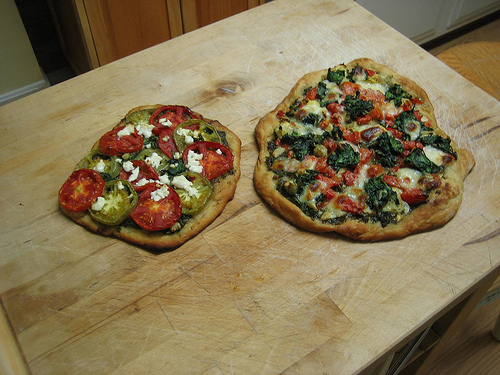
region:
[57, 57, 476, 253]
two home made vegetable pizzas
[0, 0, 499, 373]
pizzas on wooden scratched table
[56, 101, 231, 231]
green and red tomato slices on left pizza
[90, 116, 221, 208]
feta cheese on left pizza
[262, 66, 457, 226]
spinach on right pizza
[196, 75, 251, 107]
dark spot on wooden table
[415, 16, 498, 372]
wooden floor underneath table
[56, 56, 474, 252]
both pizzas have bread crusts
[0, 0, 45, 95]
yellow wall behind table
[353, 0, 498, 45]
white cabinets behind table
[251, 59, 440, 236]
this is a pizza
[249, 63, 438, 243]
the pizza is big in color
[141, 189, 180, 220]
the tomato is on the pizza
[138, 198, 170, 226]
the tomato is red in color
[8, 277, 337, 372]
the table is brown in color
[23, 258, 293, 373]
the table is wooden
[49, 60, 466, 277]
the pizza are two in number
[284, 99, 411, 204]
the pizza is spicy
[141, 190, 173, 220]
the tomato is sliced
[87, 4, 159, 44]
the board is brown in color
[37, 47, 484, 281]
Two pizzas are on the table.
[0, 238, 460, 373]
The table is made of wood.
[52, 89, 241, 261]
The pizza contains tomatoes.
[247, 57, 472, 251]
The pizza contains vegetables.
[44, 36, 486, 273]
The pizzas are cooked.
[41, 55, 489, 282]
The pizzas contain cheese.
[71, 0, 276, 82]
A cabinet is behind the table.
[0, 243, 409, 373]
The wood contains grains.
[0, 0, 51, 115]
The wall is green.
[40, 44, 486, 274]
The pizzas have not been sliced.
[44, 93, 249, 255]
small hand tossed pizza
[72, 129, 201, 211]
feta cheese on a hand tossed pizza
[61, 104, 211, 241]
green tomatoes on a hand tossed pizza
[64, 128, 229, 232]
red tomatoes on a hand tossed pizza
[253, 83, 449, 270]
medium hand tossed pizza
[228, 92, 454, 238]
spinach on a hand tossed pizza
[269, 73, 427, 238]
white cheese on a hand tossed pizza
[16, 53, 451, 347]
karge wooden butcher block table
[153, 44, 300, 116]
large knott in the block table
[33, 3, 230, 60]
brown wooden cabinet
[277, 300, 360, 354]
part of a table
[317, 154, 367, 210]
part of a pizza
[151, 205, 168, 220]
part of a tomato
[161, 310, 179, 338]
a line on the table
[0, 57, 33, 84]
part of the wall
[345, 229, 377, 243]
edge of a pizza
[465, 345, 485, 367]
part of the floor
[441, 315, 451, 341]
part of a stand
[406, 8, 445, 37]
part of a cupboard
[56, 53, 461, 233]
two pizzas on a table